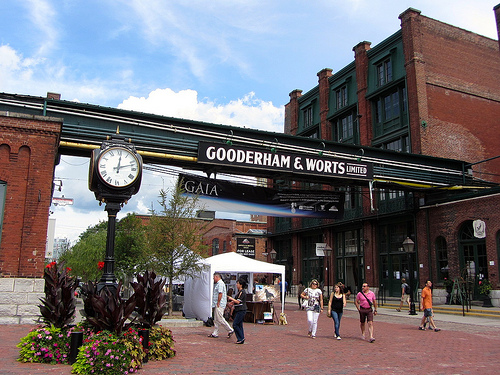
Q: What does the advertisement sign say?
A: Gooderham & Worts.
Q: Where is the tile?
A: In the walking area.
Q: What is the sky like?
A: Partially cloudy.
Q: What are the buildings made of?
A: Red brick.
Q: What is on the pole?
A: The clock.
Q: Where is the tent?
A: On the sidewalk.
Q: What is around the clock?
A: Flowers.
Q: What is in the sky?
A: Clouds.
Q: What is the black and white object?
A: A clock.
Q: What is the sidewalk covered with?
A: Red brick.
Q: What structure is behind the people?
A: A tall red building.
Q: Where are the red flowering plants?
A: Below the clock.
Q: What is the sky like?
A: Blue with white clouds.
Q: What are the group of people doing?
A: Walking.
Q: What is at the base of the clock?
A: A group of bushes and shrubberies.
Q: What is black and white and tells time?
A: The clock on the post.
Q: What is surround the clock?
A: Flowers and plants.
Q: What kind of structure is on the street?
A: White tents.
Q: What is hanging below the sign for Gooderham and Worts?
A: A banner with GAIA written on it.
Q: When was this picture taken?
A: Daytime.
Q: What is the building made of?
A: Bricks.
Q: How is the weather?
A: Sunny.